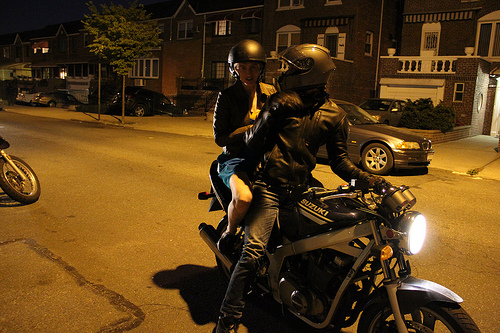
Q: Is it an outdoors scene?
A: Yes, it is outdoors.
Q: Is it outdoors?
A: Yes, it is outdoors.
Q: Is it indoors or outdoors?
A: It is outdoors.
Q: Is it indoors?
A: No, it is outdoors.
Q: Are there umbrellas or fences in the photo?
A: No, there are no fences or umbrellas.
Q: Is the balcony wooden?
A: Yes, the balcony is wooden.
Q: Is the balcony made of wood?
A: Yes, the balcony is made of wood.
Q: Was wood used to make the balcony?
A: Yes, the balcony is made of wood.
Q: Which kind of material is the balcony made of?
A: The balcony is made of wood.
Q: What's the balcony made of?
A: The balcony is made of wood.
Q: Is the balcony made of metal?
A: No, the balcony is made of wood.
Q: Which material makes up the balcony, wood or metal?
A: The balcony is made of wood.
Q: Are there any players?
A: No, there are no players.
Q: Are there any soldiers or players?
A: No, there are no players or soldiers.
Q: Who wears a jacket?
A: The driver wears a jacket.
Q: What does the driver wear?
A: The driver wears a jacket.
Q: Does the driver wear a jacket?
A: Yes, the driver wears a jacket.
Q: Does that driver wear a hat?
A: No, the driver wears a jacket.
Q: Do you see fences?
A: No, there are no fences.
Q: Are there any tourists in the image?
A: No, there are no tourists.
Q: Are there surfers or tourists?
A: No, there are no tourists or surfers.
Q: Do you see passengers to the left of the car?
A: Yes, there is a passenger to the left of the car.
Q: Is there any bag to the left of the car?
A: No, there is a passenger to the left of the car.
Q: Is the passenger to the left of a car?
A: Yes, the passenger is to the left of a car.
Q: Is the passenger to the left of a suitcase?
A: No, the passenger is to the left of a car.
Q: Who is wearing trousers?
A: The passenger is wearing trousers.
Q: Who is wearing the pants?
A: The passenger is wearing trousers.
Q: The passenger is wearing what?
A: The passenger is wearing pants.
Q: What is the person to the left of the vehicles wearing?
A: The passenger is wearing pants.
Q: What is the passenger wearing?
A: The passenger is wearing pants.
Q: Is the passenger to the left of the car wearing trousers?
A: Yes, the passenger is wearing trousers.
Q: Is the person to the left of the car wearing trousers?
A: Yes, the passenger is wearing trousers.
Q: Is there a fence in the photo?
A: No, there are no fences.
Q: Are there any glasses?
A: No, there are no glasses.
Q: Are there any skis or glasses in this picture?
A: No, there are no glasses or skis.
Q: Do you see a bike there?
A: Yes, there is a bike.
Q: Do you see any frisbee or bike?
A: Yes, there is a bike.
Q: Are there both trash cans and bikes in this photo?
A: No, there is a bike but no trash cans.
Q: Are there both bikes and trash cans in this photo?
A: No, there is a bike but no trash cans.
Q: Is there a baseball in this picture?
A: No, there are no baseballs.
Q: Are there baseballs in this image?
A: No, there are no baseballs.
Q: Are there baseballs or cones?
A: No, there are no baseballs or cones.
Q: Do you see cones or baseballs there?
A: No, there are no baseballs or cones.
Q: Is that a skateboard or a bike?
A: That is a bike.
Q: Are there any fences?
A: No, there are no fences.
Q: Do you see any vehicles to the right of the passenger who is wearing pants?
A: Yes, there are vehicles to the right of the passenger.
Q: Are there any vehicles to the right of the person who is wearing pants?
A: Yes, there are vehicles to the right of the passenger.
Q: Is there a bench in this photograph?
A: No, there are no benches.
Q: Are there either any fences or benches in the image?
A: No, there are no benches or fences.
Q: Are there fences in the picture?
A: No, there are no fences.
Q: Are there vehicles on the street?
A: Yes, there are vehicles on the street.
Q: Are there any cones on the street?
A: No, there are vehicles on the street.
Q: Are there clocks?
A: No, there are no clocks.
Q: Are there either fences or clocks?
A: No, there are no clocks or fences.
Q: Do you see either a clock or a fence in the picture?
A: No, there are no clocks or fences.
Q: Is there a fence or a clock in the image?
A: No, there are no clocks or fences.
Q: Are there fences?
A: No, there are no fences.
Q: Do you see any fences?
A: No, there are no fences.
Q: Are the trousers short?
A: Yes, the trousers are short.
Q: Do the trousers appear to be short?
A: Yes, the trousers are short.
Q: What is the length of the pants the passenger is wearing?
A: The trousers are short.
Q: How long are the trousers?
A: The trousers are short.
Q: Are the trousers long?
A: No, the trousers are short.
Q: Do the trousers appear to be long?
A: No, the trousers are short.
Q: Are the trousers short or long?
A: The trousers are short.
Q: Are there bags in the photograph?
A: No, there are no bags.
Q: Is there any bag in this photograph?
A: No, there are no bags.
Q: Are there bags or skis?
A: No, there are no bags or skis.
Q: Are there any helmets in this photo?
A: Yes, there is a helmet.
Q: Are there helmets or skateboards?
A: Yes, there is a helmet.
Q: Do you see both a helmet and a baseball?
A: No, there is a helmet but no baseballs.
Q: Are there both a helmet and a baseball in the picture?
A: No, there is a helmet but no baseballs.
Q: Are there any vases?
A: No, there are no vases.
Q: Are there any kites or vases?
A: No, there are no vases or kites.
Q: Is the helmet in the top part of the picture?
A: Yes, the helmet is in the top of the image.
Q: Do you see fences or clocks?
A: No, there are no fences or clocks.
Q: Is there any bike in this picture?
A: Yes, there is a bike.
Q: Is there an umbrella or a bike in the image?
A: Yes, there is a bike.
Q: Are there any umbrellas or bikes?
A: Yes, there is a bike.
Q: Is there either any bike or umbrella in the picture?
A: Yes, there is a bike.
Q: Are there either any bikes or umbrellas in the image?
A: Yes, there is a bike.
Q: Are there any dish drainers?
A: No, there are no dish drainers.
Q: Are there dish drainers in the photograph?
A: No, there are no dish drainers.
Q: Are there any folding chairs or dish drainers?
A: No, there are no dish drainers or folding chairs.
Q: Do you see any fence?
A: No, there are no fences.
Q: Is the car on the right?
A: Yes, the car is on the right of the image.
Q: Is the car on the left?
A: No, the car is on the right of the image.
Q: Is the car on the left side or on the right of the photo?
A: The car is on the right of the image.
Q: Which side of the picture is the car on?
A: The car is on the right of the image.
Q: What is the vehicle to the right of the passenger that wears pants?
A: The vehicle is a car.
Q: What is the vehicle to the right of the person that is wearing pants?
A: The vehicle is a car.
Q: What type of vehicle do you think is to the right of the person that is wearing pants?
A: The vehicle is a car.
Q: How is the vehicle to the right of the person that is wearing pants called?
A: The vehicle is a car.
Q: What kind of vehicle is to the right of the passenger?
A: The vehicle is a car.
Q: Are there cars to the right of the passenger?
A: Yes, there is a car to the right of the passenger.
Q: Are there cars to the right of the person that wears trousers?
A: Yes, there is a car to the right of the passenger.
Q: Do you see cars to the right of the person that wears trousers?
A: Yes, there is a car to the right of the passenger.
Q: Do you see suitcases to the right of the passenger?
A: No, there is a car to the right of the passenger.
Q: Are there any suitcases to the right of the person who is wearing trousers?
A: No, there is a car to the right of the passenger.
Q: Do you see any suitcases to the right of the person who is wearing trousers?
A: No, there is a car to the right of the passenger.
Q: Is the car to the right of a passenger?
A: Yes, the car is to the right of a passenger.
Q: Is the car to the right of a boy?
A: No, the car is to the right of a passenger.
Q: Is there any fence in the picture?
A: No, there are no fences.